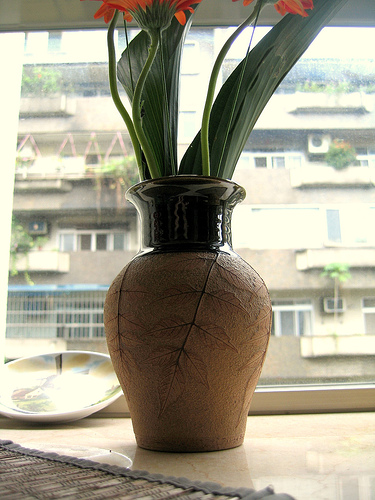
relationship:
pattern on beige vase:
[113, 246, 264, 409] [104, 181, 274, 454]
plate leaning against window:
[2, 348, 127, 427] [1, 14, 371, 385]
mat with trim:
[0, 439, 289, 500] [0, 437, 299, 499]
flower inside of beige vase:
[231, 0, 318, 17] [104, 181, 274, 454]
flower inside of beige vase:
[91, 0, 202, 25] [104, 181, 274, 454]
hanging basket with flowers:
[316, 128, 360, 181] [317, 123, 363, 156]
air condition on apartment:
[322, 295, 353, 311] [294, 190, 373, 270]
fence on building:
[7, 292, 110, 363] [15, 38, 358, 355]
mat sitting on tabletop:
[0, 439, 289, 500] [0, 409, 374, 498]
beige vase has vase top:
[104, 181, 274, 454] [125, 174, 249, 253]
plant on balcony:
[25, 65, 60, 95] [17, 92, 76, 117]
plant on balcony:
[17, 150, 33, 164] [15, 170, 129, 191]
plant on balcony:
[98, 153, 137, 187] [15, 170, 129, 191]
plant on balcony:
[12, 218, 39, 273] [7, 250, 68, 273]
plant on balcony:
[325, 136, 357, 169] [289, 160, 374, 194]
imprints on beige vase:
[147, 251, 212, 272] [104, 181, 274, 454]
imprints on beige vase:
[212, 260, 257, 299] [104, 181, 274, 454]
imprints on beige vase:
[204, 286, 251, 318] [104, 181, 274, 454]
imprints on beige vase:
[144, 282, 198, 313] [104, 181, 274, 454]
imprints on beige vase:
[192, 317, 239, 352] [104, 181, 274, 454]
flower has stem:
[91, 0, 205, 30] [131, 30, 165, 179]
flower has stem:
[231, 0, 318, 17] [200, 3, 264, 174]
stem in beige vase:
[104, 7, 149, 184] [104, 181, 274, 454]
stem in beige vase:
[131, 30, 165, 179] [104, 181, 274, 454]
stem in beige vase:
[200, 3, 264, 174] [104, 181, 274, 454]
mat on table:
[34, 459, 82, 498] [23, 422, 131, 460]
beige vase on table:
[104, 181, 274, 454] [23, 422, 131, 460]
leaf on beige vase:
[156, 358, 186, 424] [104, 181, 274, 454]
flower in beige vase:
[231, 0, 318, 17] [80, 163, 299, 463]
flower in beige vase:
[91, 0, 205, 30] [80, 163, 299, 463]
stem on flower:
[131, 30, 165, 179] [91, 0, 205, 30]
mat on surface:
[0, 439, 289, 500] [0, 407, 374, 499]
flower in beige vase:
[264, 0, 319, 17] [104, 181, 274, 454]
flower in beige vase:
[91, 0, 202, 25] [104, 181, 274, 454]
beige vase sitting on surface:
[104, 181, 274, 454] [0, 407, 374, 499]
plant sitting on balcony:
[324, 137, 356, 171] [288, 165, 372, 189]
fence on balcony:
[7, 292, 105, 340] [4, 285, 109, 355]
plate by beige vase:
[2, 348, 127, 427] [104, 181, 274, 454]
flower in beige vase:
[91, 0, 205, 30] [104, 181, 274, 454]